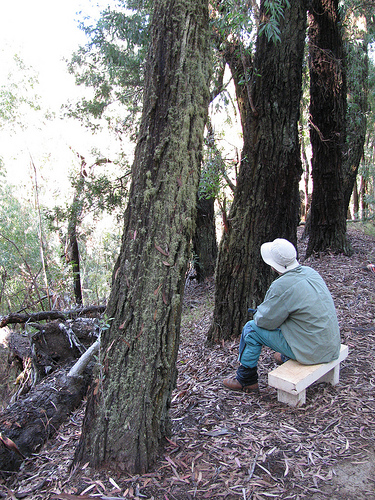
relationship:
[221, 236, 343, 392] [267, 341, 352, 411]
person sitting on bench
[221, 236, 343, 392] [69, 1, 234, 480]
person next to tree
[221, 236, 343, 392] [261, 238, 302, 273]
person wearing hat